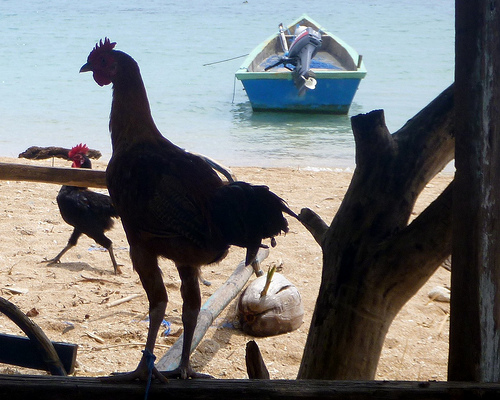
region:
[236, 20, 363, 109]
a boat in the water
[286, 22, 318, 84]
the motor on the boat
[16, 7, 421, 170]
the water under the boat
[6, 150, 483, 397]
sand on the beach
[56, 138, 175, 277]
a rooster walking on the beach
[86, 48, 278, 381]
a rooster standing on a log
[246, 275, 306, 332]
a rock on the beach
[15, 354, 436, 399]
a piece of wood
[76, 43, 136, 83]
the head of the rooster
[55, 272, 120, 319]
sticks on the sand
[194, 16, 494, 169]
a boat in the water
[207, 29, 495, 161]
a small boat in the water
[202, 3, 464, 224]
a blue boat in the water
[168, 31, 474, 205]
a small blue boat in the water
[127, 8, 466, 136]
a body of water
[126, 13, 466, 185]
a body of blue water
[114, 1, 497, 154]
a body of water that is blue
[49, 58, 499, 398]
chicken on the sand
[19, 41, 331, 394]
chicken on the beach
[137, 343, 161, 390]
a piece of blue string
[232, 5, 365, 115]
a bright blue boat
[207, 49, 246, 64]
the rope to the anchor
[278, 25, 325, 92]
a black boat motor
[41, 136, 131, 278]
a chicken on the beach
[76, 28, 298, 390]
a black and brown chicken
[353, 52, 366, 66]
a small wood pole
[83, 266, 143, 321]
a few sticks in the dirt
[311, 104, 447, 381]
a smooth tree trunk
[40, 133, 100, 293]
a chicken walking on a beach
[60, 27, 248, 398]
a chicken standing on a fence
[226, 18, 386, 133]
a blue boat with green trim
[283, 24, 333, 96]
a motor on a boat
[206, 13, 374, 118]
a boat in the water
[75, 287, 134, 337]
twigs and sticks on a beach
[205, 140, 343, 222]
a beach by the water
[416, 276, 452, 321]
a rock on the beach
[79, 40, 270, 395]
rooster perched on wooden fence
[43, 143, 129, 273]
rooster walking in dry sand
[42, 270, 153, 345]
sticks lying in the sand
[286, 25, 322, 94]
motor of a boat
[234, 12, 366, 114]
blue and green boat with motor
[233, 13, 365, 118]
boat sitting in the water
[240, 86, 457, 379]
part of a cut tree branch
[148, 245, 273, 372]
wooden post lying in sand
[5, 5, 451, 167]
boat floating in water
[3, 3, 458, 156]
water is calm and blue